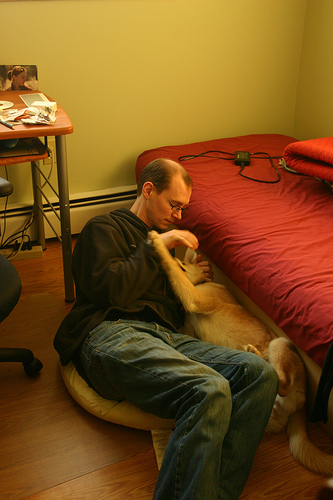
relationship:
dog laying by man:
[149, 229, 331, 475] [48, 156, 282, 494]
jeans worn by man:
[85, 316, 279, 498] [48, 156, 282, 494]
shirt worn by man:
[52, 206, 180, 369] [48, 156, 282, 494]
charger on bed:
[179, 145, 295, 189] [135, 122, 332, 371]